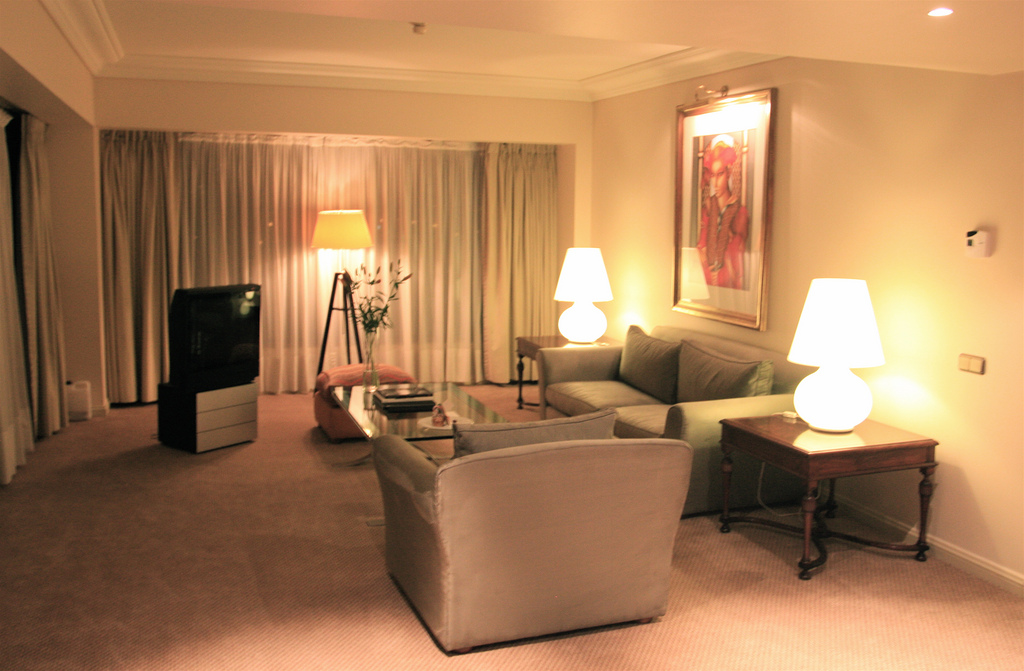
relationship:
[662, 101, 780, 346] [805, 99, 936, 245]
picture on wall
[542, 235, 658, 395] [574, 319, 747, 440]
light near sofa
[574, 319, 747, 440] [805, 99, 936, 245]
sofa near wall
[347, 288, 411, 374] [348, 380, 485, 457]
flowers on table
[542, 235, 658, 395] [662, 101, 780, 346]
light on picture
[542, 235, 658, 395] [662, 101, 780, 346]
light near picture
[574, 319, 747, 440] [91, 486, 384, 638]
sofa on floor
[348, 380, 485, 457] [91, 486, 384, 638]
table on floor